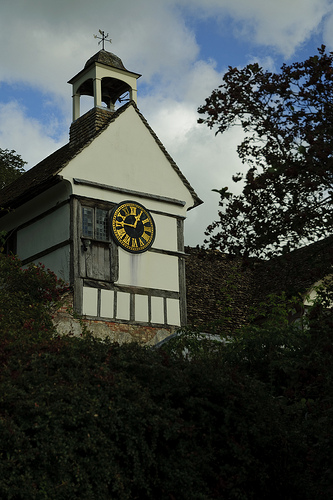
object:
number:
[130, 206, 138, 215]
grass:
[130, 205, 136, 217]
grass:
[143, 225, 152, 232]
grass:
[131, 238, 138, 249]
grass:
[113, 220, 123, 226]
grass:
[116, 228, 125, 238]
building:
[1, 28, 330, 351]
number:
[131, 236, 137, 247]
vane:
[89, 26, 112, 48]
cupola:
[66, 26, 142, 142]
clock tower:
[0, 27, 200, 335]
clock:
[110, 201, 157, 255]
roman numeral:
[129, 205, 136, 215]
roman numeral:
[141, 218, 150, 225]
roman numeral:
[131, 238, 138, 248]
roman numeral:
[117, 228, 127, 239]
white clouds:
[2, 1, 331, 245]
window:
[76, 197, 113, 284]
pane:
[87, 210, 92, 215]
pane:
[103, 232, 106, 238]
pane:
[84, 217, 87, 222]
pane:
[88, 230, 92, 234]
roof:
[0, 99, 204, 207]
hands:
[114, 220, 135, 228]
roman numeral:
[143, 225, 152, 233]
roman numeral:
[141, 232, 150, 243]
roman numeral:
[123, 234, 130, 246]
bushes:
[0, 253, 331, 495]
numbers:
[142, 217, 150, 224]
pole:
[103, 40, 105, 49]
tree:
[197, 42, 331, 272]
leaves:
[194, 60, 328, 339]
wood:
[76, 277, 185, 328]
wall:
[58, 103, 196, 329]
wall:
[184, 232, 332, 345]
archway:
[301, 273, 333, 309]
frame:
[73, 277, 188, 332]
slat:
[95, 287, 102, 319]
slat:
[112, 290, 118, 318]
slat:
[128, 294, 136, 321]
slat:
[147, 296, 152, 322]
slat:
[162, 297, 168, 324]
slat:
[72, 175, 186, 206]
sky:
[0, 0, 332, 259]